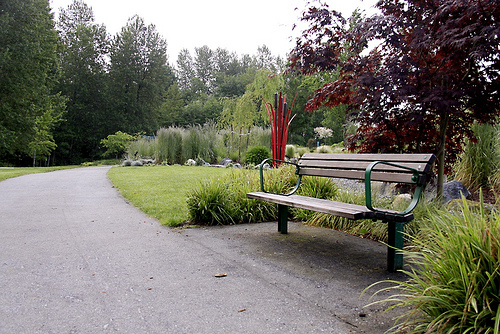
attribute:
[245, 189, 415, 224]
seat — wooden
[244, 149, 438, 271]
bench — brown, wooden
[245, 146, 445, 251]
bricks — wooden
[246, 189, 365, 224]
slat — brown, wooden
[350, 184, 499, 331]
bush — grassy, green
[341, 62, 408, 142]
tree — red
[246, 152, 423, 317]
leg — green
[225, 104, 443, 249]
bench — wooden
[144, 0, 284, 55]
sky — clear , white 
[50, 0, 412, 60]
sky — grey, cloudy 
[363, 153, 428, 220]
armrest — green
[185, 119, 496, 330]
shrubbery — bunch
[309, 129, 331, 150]
person — standing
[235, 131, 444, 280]
parkbench — metal, wood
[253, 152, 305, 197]
armrest — green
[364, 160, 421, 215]
armrest — green 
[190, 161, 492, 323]
grasses — tall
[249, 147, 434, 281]
bench — brown, light brown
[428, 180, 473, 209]
dark rock — large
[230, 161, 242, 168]
stone — decorative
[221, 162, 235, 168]
stone — decorative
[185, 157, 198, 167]
stone — decorative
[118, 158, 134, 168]
stone — decorative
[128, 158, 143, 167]
stone — decorative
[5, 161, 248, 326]
walkway — paved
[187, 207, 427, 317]
foundation — concrete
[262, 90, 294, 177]
spikey — red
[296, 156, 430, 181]
slat — brown wooden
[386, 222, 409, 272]
leg — green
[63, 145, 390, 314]
path — concrete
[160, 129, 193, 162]
plants — variety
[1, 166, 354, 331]
sidewalk — light grey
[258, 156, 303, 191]
armrest — green 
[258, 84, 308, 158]
structure — red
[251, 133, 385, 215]
bench — brown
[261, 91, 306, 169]
stalks — red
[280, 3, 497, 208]
tree — medium sized, maple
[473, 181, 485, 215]
leaf — green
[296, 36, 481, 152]
buds — red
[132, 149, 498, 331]
grass — tall, spiky , green 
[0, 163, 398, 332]
path — concrete 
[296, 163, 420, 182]
slat — brown, wooden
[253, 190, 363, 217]
slat — wooden, brown